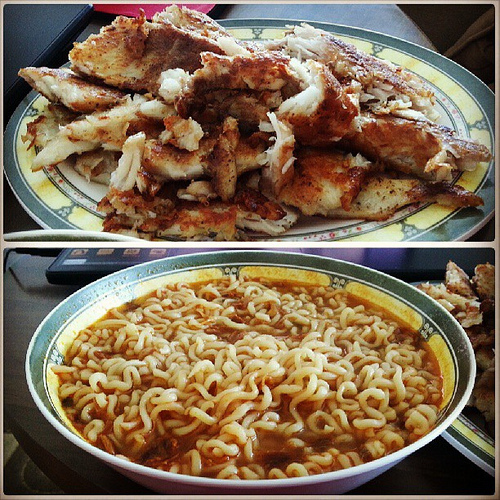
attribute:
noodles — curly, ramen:
[65, 268, 430, 475]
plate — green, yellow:
[13, 22, 493, 242]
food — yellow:
[18, 5, 490, 239]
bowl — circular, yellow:
[16, 244, 482, 498]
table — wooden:
[13, 282, 37, 320]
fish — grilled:
[17, 2, 495, 242]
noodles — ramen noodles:
[213, 351, 310, 368]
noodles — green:
[181, 286, 373, 390]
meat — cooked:
[27, 10, 480, 233]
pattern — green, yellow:
[27, 248, 475, 486]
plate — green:
[2, 21, 475, 252]